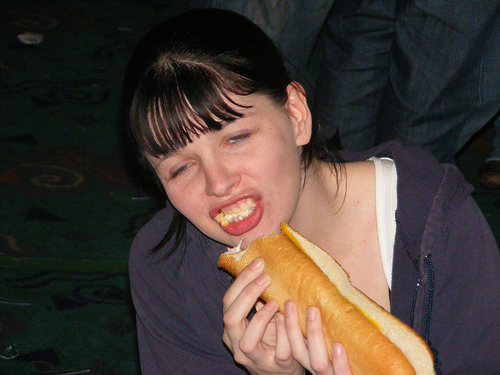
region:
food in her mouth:
[200, 202, 245, 231]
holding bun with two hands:
[211, 260, 364, 363]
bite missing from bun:
[206, 235, 283, 265]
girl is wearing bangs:
[122, 65, 285, 171]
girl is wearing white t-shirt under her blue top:
[359, 147, 444, 301]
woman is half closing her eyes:
[166, 112, 267, 178]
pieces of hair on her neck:
[309, 144, 358, 214]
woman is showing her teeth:
[208, 183, 298, 241]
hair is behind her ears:
[251, 66, 321, 164]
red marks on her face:
[199, 165, 284, 226]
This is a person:
[92, 25, 490, 369]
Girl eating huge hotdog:
[117, 5, 497, 372]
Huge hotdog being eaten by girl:
[211, 218, 435, 372]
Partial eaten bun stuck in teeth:
[211, 195, 263, 225]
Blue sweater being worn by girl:
[125, 141, 499, 373]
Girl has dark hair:
[113, 7, 356, 273]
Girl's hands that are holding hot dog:
[211, 251, 353, 373]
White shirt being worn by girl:
[367, 150, 414, 297]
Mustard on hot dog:
[338, 295, 381, 332]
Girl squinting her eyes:
[160, 127, 276, 184]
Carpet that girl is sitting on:
[1, 2, 191, 374]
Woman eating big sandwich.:
[112, 4, 494, 366]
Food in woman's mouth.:
[207, 187, 272, 241]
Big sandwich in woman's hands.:
[218, 225, 438, 373]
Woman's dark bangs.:
[117, 59, 261, 161]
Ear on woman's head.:
[277, 80, 314, 151]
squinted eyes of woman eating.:
[158, 109, 285, 186]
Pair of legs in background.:
[207, 2, 491, 129]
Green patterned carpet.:
[1, 0, 116, 362]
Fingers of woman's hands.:
[217, 257, 344, 372]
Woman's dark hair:
[117, 1, 348, 256]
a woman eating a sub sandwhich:
[105, 2, 475, 368]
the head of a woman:
[106, 14, 323, 249]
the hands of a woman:
[204, 255, 353, 372]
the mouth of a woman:
[200, 189, 272, 234]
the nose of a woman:
[198, 165, 240, 197]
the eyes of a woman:
[142, 128, 261, 180]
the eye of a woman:
[218, 125, 258, 150]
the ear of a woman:
[277, 80, 317, 145]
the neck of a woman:
[291, 148, 329, 235]